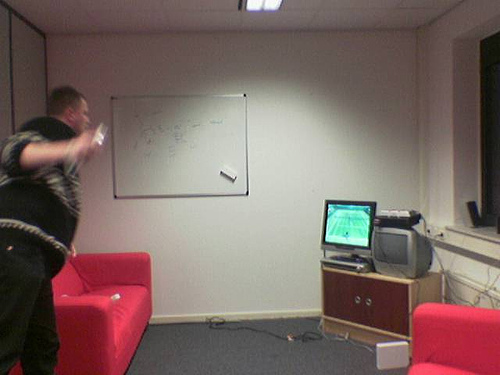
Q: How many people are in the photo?
A: One.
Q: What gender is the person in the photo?
A: Male.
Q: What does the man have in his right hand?
A: A game controller.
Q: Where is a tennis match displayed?
A: On the computer screen.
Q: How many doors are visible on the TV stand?
A: Two.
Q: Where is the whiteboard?
A: Hanging on the back wall.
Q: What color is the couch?
A: Red.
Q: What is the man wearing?
A: A sweater and black jeans.